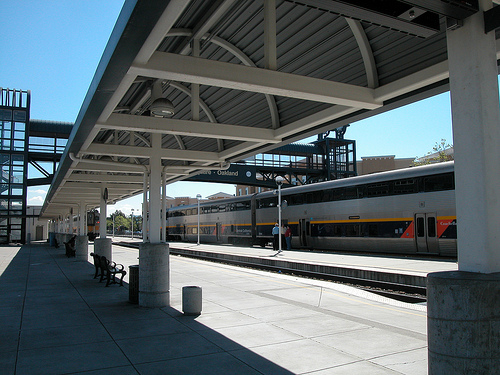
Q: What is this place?
A: A train station.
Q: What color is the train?
A: Silver.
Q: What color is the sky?
A: Blue.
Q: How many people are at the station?
A: Two.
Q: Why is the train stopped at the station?
A: To load and unload passengers.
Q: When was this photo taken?
A: During the daytime.